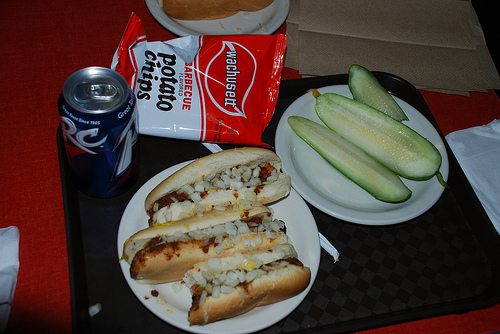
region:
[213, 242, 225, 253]
piece of chopped white onion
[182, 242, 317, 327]
bitten chilli dog on a white plate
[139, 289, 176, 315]
chilli stains on a white plate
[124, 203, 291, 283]
whole chilli dog on a plate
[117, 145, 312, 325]
three chilli dogs on a plate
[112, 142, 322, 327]
chilli dogs topped with chopped onions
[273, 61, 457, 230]
sliced pickles on a white plate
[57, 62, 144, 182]
blue can of RC soda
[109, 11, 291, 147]
red and white bag of barbecue chips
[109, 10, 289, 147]
bag of barbeque flavored chips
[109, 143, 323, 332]
Three hot dogs on a plate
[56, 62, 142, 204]
A blue soda can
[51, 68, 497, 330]
A black plastic tray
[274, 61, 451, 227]
Cantaloupe on a plate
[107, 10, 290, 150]
A bag of potato chips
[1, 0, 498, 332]
The table is red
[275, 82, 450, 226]
A round white plate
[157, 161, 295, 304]
Onions on hot dogs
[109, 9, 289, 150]
A red and white bag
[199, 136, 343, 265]
A white straw on tray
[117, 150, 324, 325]
three chili dogs on a plate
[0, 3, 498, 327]
a red table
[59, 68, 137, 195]
an aluminum can of soda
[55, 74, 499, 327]
black plastic cafeteria tray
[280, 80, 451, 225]
white plate with pickles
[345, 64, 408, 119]
half-eaten pickle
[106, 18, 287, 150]
red and white bag of potato chips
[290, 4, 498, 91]
stack of brown paper towels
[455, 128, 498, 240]
white napkin near the pickles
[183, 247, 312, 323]
chili dog already bitten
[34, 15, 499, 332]
A large cafeteria style tray containing various food items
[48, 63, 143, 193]
a blue 12 ounce can of RC Cola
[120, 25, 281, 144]
A small bag of wachusett barbecue flavored potato chips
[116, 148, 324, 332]
a circular plate containing 3 hotdogs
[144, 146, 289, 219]
a hot dog full of condiments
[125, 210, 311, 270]
a hot dog covered in onions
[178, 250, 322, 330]
a hot dog with a bite already taken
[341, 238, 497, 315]
a dark colored cafeteria tray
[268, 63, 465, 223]
a circular plate containing 3 pickle spears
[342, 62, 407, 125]
a partially eaten pickle spear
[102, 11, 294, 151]
Open bag of chips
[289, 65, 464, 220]
Three pickle slices on a plate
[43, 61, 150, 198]
Red white and blue soda can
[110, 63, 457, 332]
Food on white paper plates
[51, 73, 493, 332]
Black table mat for food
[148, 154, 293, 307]
Onions on top of hot dogs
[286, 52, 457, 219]
Green slices of pickle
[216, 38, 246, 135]
White logo on potato chip bag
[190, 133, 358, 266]
White straw under the plate